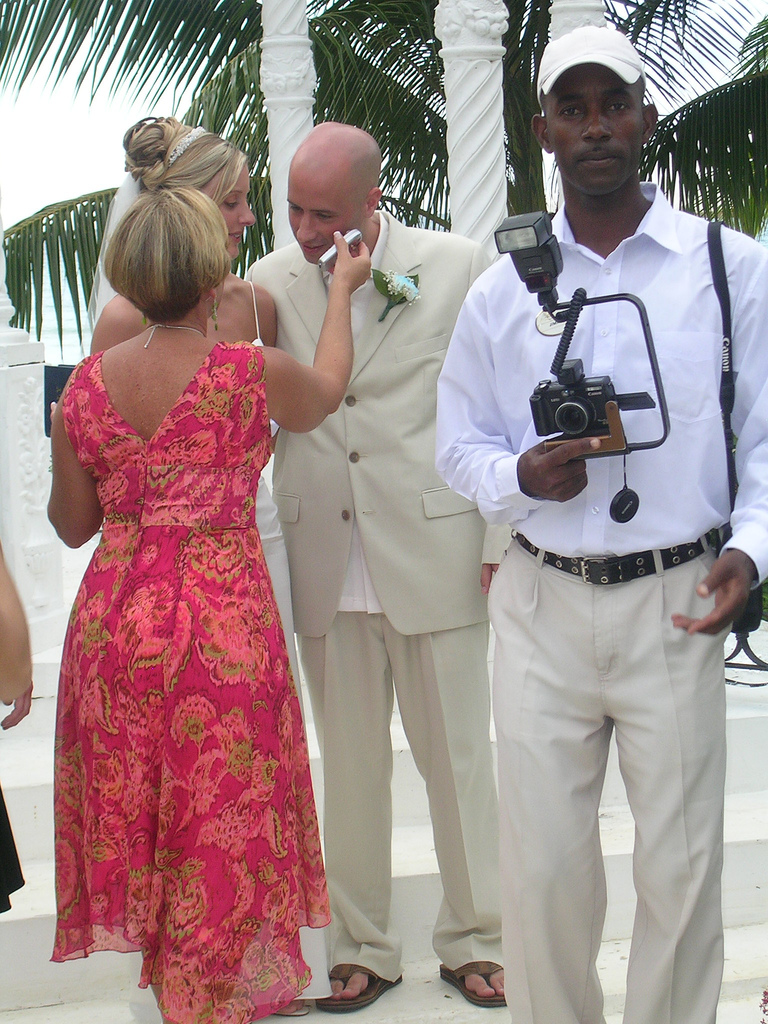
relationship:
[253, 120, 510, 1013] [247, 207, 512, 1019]
man wearing suit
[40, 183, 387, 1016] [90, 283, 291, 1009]
woman wearing dress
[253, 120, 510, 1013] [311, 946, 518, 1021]
man wearing sandles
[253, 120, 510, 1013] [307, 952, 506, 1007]
man wearing sandles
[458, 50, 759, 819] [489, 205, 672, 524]
man holds camera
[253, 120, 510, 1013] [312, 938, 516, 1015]
man wears sandles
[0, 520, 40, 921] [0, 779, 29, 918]
woman wears black dress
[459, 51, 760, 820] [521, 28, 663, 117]
man wearing cap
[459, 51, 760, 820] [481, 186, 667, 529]
man holding camera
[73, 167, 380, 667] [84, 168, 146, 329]
woman wears veil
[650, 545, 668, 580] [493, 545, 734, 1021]
loop on pants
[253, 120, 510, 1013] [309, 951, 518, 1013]
man wearing flip flops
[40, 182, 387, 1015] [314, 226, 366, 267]
woman holding cellphone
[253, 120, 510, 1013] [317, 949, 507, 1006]
man wearing sandals